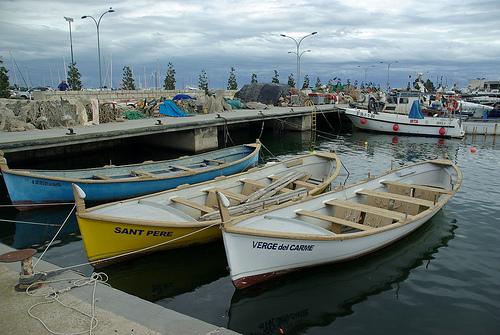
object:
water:
[424, 245, 483, 302]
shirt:
[409, 100, 426, 121]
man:
[408, 98, 426, 119]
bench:
[297, 176, 443, 232]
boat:
[211, 154, 463, 281]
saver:
[437, 125, 449, 135]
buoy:
[468, 146, 480, 153]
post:
[0, 248, 43, 295]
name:
[250, 239, 314, 251]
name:
[114, 227, 173, 239]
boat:
[75, 147, 345, 267]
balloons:
[437, 127, 448, 134]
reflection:
[234, 212, 462, 323]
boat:
[2, 143, 262, 211]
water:
[350, 144, 376, 171]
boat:
[414, 106, 494, 133]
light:
[278, 32, 289, 39]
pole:
[337, 90, 348, 102]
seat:
[297, 209, 377, 230]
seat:
[324, 196, 413, 222]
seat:
[382, 178, 450, 195]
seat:
[354, 188, 435, 210]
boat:
[344, 102, 465, 138]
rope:
[28, 270, 108, 335]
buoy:
[391, 124, 400, 131]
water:
[54, 244, 83, 261]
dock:
[0, 100, 340, 170]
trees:
[1, 54, 385, 97]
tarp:
[155, 100, 194, 117]